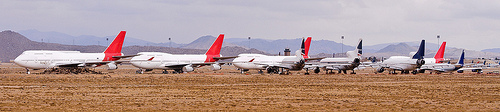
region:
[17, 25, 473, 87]
many airplanes that are red and white and blue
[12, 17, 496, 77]
mountains behind row of airplanes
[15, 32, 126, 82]
white airplane with a red tail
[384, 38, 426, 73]
white airplane with a blue tail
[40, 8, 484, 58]
cloudy sky over the mountains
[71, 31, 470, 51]
posts in the back of the airplanes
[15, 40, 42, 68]
nose of a plane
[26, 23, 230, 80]
two red and white planes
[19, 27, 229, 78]
two planes with red tails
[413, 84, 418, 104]
There is a brown ground visible here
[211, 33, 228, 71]
The tail of this plane is dark red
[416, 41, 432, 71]
The tail of this plane is dark blue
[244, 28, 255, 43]
There are silver lamps visible in the back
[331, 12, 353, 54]
There is a very light sky in the distance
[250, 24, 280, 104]
This photo has a great deal of detail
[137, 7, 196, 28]
white clouds in blue sky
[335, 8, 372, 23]
white clouds in blue sky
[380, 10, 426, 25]
white clouds in blue sky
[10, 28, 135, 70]
white plane on the airstrip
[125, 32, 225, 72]
white plane on the airstrip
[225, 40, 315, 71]
white plane on the airstrip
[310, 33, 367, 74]
white plane on the airstrip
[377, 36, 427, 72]
white plane on the airstrip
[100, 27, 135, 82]
wing of a plane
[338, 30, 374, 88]
wing of a plane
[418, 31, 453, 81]
wing of a plane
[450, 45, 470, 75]
wing of a plane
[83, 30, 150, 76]
tail of a plane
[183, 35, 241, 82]
tail of a plane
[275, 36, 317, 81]
tail of a plane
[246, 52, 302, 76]
this is a jet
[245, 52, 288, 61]
this is the body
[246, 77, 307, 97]
this is a grass area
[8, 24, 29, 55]
this is a hill